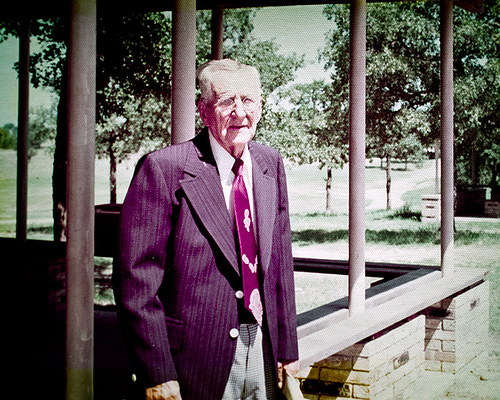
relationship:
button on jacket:
[217, 320, 238, 344] [121, 100, 336, 397]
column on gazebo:
[64, 2, 94, 399] [1, 0, 489, 398]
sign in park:
[421, 192, 438, 227] [299, 17, 464, 382]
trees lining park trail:
[306, 0, 498, 182] [297, 15, 485, 279]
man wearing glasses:
[111, 57, 305, 396] [202, 83, 265, 117]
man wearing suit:
[111, 57, 305, 396] [108, 124, 304, 390]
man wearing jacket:
[111, 57, 305, 396] [139, 133, 307, 351]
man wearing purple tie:
[95, 45, 402, 396] [228, 156, 263, 332]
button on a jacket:
[230, 287, 245, 302] [101, 126, 338, 397]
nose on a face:
[228, 93, 246, 121] [213, 70, 259, 147]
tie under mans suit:
[227, 159, 268, 326] [108, 124, 304, 390]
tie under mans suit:
[227, 159, 456, 219] [108, 124, 304, 390]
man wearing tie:
[111, 57, 305, 396] [232, 158, 263, 328]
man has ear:
[111, 57, 305, 396] [193, 93, 211, 129]